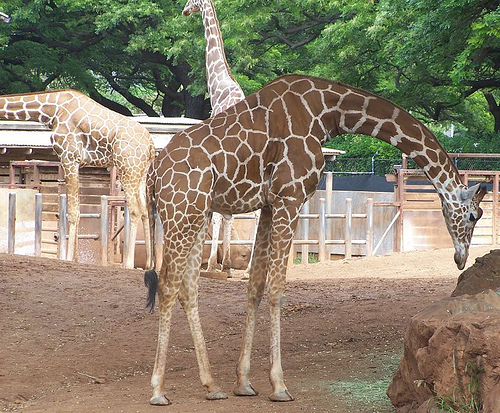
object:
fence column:
[97, 192, 112, 267]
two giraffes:
[0, 71, 485, 406]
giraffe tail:
[140, 176, 160, 315]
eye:
[466, 213, 478, 224]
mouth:
[452, 248, 467, 271]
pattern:
[260, 137, 287, 173]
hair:
[141, 269, 161, 314]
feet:
[265, 375, 295, 402]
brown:
[0, 253, 113, 346]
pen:
[0, 113, 498, 276]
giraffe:
[140, 72, 488, 407]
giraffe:
[0, 87, 157, 271]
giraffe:
[178, 0, 270, 280]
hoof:
[230, 371, 256, 398]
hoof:
[200, 379, 228, 401]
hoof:
[147, 384, 172, 406]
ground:
[0, 243, 499, 413]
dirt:
[0, 245, 499, 413]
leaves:
[379, 78, 393, 89]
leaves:
[324, 66, 335, 74]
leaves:
[183, 39, 198, 50]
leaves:
[486, 30, 494, 40]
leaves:
[147, 37, 160, 48]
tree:
[0, 0, 499, 172]